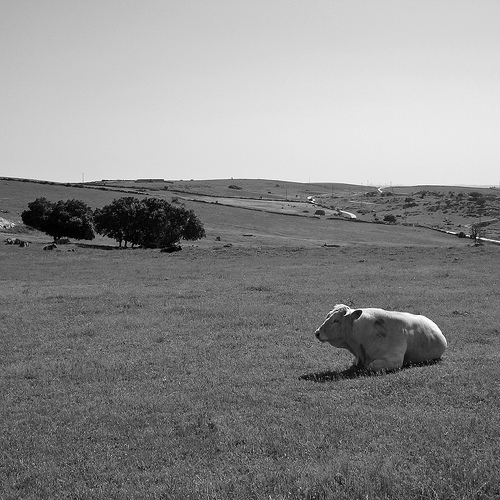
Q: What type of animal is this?
A: The animal is a cow.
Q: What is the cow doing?
A: The cow is resting.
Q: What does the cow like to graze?
A: The cow likes to graze grass.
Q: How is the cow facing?
A: The cow is facing left.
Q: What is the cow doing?
A: The cow is lying down.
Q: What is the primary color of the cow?
A: The cow is white .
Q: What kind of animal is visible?
A: Cow.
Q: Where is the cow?
A: Field.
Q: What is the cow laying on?
A: Ground.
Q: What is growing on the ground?
A: Grass.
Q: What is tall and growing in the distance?
A: Trees.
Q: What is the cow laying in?
A: Grass.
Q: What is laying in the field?
A: Cow.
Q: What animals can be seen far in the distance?
A: Cows.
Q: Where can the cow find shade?
A: Under the trees.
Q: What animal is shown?
A: Cow.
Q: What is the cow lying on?
A: Grass.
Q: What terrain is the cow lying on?
A: Hillside.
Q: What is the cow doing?
A: Laying down.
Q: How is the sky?
A: Clear and sunny.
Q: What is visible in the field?
A: A cow.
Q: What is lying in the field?
A: A cow is visible.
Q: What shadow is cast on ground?
A: A cow.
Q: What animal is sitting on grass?
A: A cow.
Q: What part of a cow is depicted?
A: The front part of a cow.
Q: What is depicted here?
A: The left side of cow.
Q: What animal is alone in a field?
A: A cow.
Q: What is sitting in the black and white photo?
A: A cow.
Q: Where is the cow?
A: In a big field.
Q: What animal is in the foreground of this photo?
A: Cow.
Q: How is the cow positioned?
A: Laying down.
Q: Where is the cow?
A: Pasture.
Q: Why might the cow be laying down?
A: Resting.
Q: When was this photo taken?
A: Daytime.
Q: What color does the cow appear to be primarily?
A: White.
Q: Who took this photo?
A: Photographer.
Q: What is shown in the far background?
A: Sky.